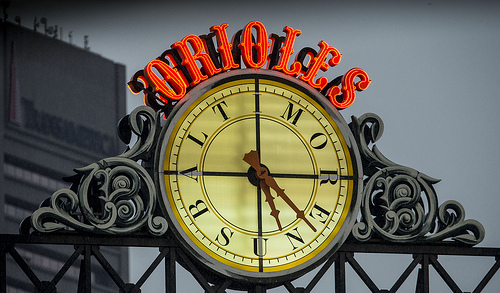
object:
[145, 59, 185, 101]
letter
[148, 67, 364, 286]
clock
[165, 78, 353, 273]
face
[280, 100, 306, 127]
letter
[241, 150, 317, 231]
hand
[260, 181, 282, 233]
hand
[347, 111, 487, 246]
scrollwork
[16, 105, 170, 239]
scrollwork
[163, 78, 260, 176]
quarter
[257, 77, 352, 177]
quarter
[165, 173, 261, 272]
quarter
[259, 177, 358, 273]
quarter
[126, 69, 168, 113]
letter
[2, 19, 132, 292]
building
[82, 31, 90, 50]
item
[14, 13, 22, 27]
item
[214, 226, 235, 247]
letter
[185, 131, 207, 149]
letter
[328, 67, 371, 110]
letter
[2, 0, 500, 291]
sky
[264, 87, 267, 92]
tick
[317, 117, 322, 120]
tick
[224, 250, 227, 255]
tick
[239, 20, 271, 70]
letter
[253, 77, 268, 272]
line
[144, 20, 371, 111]
name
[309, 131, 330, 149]
letter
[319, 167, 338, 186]
letter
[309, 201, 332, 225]
letter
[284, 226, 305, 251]
letter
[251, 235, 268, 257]
letter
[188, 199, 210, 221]
letter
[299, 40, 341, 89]
letter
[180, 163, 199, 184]
letter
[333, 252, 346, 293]
post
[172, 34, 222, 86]
letter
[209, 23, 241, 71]
letter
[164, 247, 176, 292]
post